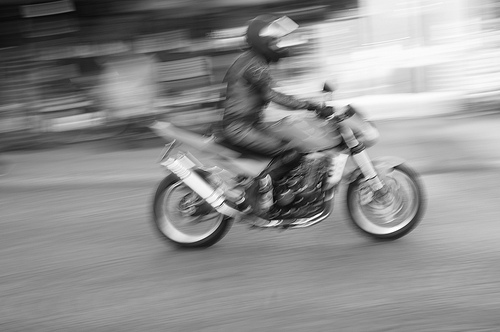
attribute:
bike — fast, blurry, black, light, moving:
[153, 15, 425, 249]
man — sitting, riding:
[221, 13, 334, 208]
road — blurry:
[1, 137, 499, 331]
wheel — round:
[154, 170, 232, 248]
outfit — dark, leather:
[221, 50, 334, 210]